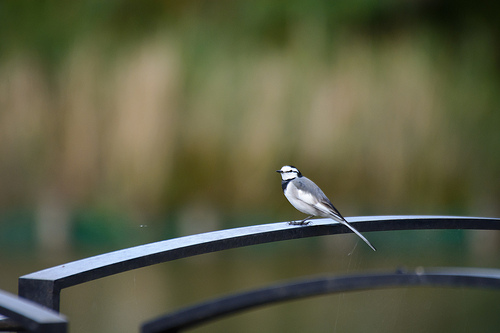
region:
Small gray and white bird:
[276, 161, 376, 253]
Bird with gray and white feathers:
[274, 158, 378, 255]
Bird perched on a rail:
[275, 158, 375, 256]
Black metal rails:
[2, 207, 497, 332]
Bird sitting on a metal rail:
[275, 159, 377, 255]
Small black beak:
[276, 168, 283, 176]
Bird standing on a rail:
[275, 163, 375, 251]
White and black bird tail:
[337, 218, 377, 253]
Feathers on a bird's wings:
[310, 190, 345, 222]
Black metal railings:
[0, 204, 499, 331]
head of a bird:
[272, 159, 302, 179]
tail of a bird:
[330, 195, 377, 250]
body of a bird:
[287, 172, 324, 216]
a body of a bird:
[277, 171, 339, 232]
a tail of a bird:
[336, 212, 378, 247]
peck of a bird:
[267, 166, 285, 177]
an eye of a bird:
[280, 168, 287, 176]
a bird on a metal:
[244, 161, 434, 314]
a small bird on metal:
[253, 132, 487, 327]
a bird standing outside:
[212, 118, 464, 326]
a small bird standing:
[229, 143, 396, 275]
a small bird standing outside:
[218, 111, 490, 298]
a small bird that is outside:
[228, 132, 421, 329]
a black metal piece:
[242, 115, 465, 323]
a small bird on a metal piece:
[184, 122, 425, 312]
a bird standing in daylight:
[230, 151, 497, 302]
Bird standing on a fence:
[278, 158, 360, 252]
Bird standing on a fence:
[273, 149, 380, 254]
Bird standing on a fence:
[271, 155, 385, 258]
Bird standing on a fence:
[261, 153, 385, 270]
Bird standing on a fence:
[267, 155, 372, 260]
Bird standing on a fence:
[270, 155, 381, 257]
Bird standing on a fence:
[262, 155, 387, 265]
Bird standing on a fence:
[278, 152, 379, 253]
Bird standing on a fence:
[263, 157, 388, 257]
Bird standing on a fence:
[261, 155, 394, 272]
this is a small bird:
[245, 76, 417, 308]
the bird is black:
[294, 189, 354, 195]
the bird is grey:
[254, 159, 388, 280]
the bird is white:
[236, 186, 356, 201]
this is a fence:
[190, 225, 276, 330]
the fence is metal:
[122, 185, 230, 290]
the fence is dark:
[186, 180, 256, 245]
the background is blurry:
[142, 138, 183, 209]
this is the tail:
[332, 163, 387, 291]